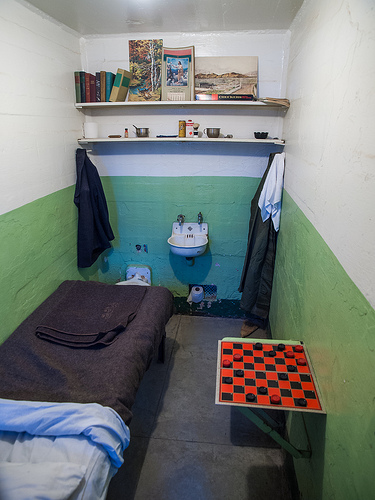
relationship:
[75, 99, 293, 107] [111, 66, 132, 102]
shelf with book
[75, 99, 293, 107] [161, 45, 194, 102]
shelf with calendar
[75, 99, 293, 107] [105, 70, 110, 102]
shelf with book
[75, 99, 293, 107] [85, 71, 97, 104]
shelf with book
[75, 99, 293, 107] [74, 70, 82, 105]
shelf with book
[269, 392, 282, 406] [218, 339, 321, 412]
checker on board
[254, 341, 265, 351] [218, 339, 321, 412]
checker on board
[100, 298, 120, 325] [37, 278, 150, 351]
printing on blanket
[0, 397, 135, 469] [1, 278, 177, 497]
sheet on bed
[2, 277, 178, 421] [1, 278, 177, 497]
blanket covering bed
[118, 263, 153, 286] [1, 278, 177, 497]
toilet end of bed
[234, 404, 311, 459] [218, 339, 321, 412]
support for table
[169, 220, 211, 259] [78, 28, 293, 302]
sink attached to wall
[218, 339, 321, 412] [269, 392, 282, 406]
checkerboard with checker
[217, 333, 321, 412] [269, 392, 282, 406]
board with checker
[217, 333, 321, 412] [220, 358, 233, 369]
board with checker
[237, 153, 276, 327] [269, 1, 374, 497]
coat on wall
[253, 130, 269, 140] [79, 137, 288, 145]
ashtray on shelf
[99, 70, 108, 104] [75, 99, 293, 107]
book on shelf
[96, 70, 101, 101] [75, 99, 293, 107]
book on shelf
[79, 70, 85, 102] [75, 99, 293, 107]
book on shelf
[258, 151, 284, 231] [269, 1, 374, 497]
towel on wall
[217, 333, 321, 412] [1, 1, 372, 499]
board in room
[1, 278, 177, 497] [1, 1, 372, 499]
bed in room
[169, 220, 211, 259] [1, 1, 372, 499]
sink in room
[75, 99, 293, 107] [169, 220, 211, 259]
shelf above sink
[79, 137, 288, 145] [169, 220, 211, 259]
shelf above sink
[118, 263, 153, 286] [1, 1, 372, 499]
toilet in room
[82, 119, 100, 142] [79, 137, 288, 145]
paper on shelf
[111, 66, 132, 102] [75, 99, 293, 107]
book on shelf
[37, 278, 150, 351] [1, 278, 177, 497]
towel on bed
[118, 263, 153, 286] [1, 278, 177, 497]
toilet front of bed